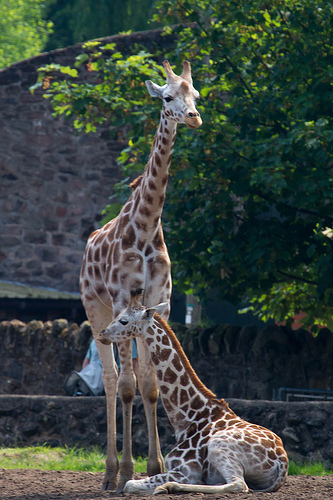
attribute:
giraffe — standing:
[109, 61, 269, 395]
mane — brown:
[169, 343, 210, 389]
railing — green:
[273, 384, 332, 403]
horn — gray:
[161, 57, 174, 79]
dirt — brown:
[4, 460, 88, 499]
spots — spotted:
[90, 230, 124, 268]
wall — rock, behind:
[1, 17, 206, 297]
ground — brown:
[1, 468, 331, 499]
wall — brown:
[4, 311, 326, 466]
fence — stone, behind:
[0, 314, 331, 461]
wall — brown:
[0, 19, 248, 301]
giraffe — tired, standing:
[79, 59, 201, 496]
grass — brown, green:
[4, 442, 326, 477]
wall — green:
[6, 323, 328, 395]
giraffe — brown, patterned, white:
[94, 283, 290, 498]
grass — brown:
[15, 443, 89, 469]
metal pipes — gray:
[278, 385, 328, 406]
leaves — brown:
[199, 15, 281, 123]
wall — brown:
[7, 321, 75, 389]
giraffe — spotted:
[86, 292, 271, 472]